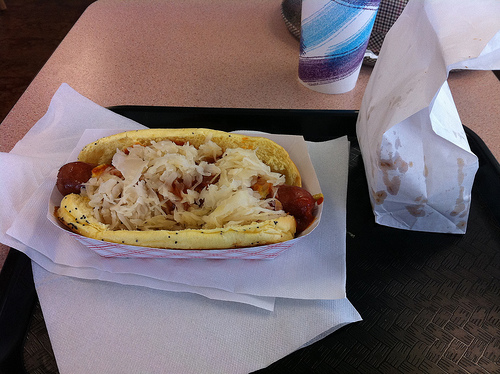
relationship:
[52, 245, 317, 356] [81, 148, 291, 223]
napkins underneath hot dog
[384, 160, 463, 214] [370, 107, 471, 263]
grease coming through bag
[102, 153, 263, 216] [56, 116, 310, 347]
sour kraut on hot dog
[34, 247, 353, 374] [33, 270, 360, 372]
stack of white napkins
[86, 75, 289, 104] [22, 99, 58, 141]
table brown and speckled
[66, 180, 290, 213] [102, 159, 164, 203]
hot dog  cooked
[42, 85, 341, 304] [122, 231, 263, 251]
bun has poppy seeds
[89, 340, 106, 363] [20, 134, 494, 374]
small part of white napkin on table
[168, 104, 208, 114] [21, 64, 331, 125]
small part of tan table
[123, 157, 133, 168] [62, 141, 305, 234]
one of onions on hot dog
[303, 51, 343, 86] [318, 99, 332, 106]
bottom part of white blue and purple cup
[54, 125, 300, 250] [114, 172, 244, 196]
bun used for hot dog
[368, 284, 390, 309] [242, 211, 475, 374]
small part of black tray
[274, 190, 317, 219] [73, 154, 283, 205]
right end of hot dog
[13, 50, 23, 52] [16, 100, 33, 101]
small part of brown floor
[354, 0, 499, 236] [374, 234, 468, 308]
bag on tray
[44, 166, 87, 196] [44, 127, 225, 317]
left end of hot dog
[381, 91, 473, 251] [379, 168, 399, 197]
bag with grease grease spot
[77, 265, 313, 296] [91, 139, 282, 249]
napkin under hot dog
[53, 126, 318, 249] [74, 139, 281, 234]
hot dog has sour kraut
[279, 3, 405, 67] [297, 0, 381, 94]
hat by cup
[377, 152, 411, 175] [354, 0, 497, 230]
grease spot on bag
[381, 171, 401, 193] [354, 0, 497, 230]
grease spot on bag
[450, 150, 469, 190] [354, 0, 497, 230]
grease spot on bag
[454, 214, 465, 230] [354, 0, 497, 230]
grease spot on bag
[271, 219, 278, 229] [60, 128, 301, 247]
seed on bun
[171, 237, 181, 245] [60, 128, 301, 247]
seed on bun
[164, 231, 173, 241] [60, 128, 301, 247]
seed on bun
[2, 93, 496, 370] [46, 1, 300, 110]
tray on table